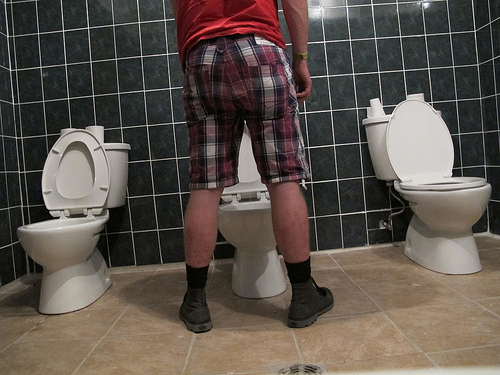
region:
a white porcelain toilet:
[17, 123, 132, 313]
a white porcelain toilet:
[365, 96, 492, 275]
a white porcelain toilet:
[205, 108, 302, 301]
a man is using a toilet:
[163, 3, 335, 328]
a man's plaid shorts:
[179, 33, 311, 190]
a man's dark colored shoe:
[287, 283, 332, 325]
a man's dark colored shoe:
[177, 297, 211, 332]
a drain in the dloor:
[280, 365, 320, 374]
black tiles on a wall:
[1, 0, 498, 288]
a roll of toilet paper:
[364, 92, 384, 119]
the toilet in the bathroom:
[10, 122, 128, 321]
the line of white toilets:
[9, 119, 499, 319]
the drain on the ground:
[276, 359, 325, 374]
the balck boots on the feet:
[171, 282, 337, 339]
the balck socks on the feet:
[185, 259, 315, 291]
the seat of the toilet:
[42, 130, 110, 207]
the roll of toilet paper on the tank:
[89, 124, 107, 141]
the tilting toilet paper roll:
[364, 90, 386, 122]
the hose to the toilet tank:
[380, 181, 406, 232]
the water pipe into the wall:
[379, 212, 398, 233]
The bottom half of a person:
[144, 2, 341, 341]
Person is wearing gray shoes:
[161, 265, 343, 341]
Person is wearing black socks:
[177, 246, 319, 299]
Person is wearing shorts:
[156, 35, 321, 205]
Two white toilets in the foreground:
[5, 85, 495, 327]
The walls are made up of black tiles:
[0, 2, 499, 286]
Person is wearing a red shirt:
[167, 3, 300, 66]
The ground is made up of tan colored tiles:
[0, 228, 499, 373]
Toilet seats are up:
[3, 88, 498, 327]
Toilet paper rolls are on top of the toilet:
[51, 115, 124, 160]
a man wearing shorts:
[158, 36, 381, 205]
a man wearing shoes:
[153, 255, 358, 335]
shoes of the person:
[138, 248, 380, 371]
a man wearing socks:
[177, 242, 346, 294]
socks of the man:
[164, 250, 374, 287]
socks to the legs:
[185, 252, 365, 297]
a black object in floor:
[252, 325, 327, 373]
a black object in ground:
[259, 343, 333, 372]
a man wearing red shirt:
[179, 5, 285, 42]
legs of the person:
[171, 152, 364, 269]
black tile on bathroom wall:
[39, 32, 64, 67]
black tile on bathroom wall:
[64, 27, 90, 62]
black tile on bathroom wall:
[86, 25, 116, 61]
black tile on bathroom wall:
[325, 40, 353, 75]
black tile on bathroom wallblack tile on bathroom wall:
[351, 38, 380, 73]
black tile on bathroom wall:
[378, 70, 406, 106]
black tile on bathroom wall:
[126, 196, 159, 230]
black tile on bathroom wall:
[132, 229, 162, 264]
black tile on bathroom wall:
[315, 215, 341, 250]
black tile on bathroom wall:
[341, 213, 368, 248]